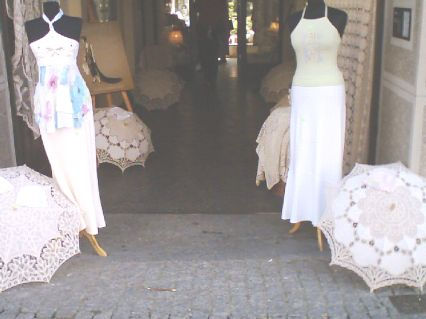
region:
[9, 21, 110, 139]
white and blue dress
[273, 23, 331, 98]
yellow dress on mannequin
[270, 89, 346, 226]
white dress on mannequin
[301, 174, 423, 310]
white and brown umbrella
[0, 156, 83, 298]
pink and white umbrella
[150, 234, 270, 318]
sidewalk is light grey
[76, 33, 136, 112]
painting on easel near umbrella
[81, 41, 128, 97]
person shown on painting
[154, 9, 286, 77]
white lights in building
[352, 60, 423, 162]
white wall near umbrella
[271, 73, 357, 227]
white skirt on black mannequin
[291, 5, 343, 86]
white tank with embroidery on mannequin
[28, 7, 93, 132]
rainbow tank on mannequin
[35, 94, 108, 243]
white skirt on mannequin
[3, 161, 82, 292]
white umbrella with black lace design around edge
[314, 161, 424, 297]
white umbrella with overall black design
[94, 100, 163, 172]
open pink white and black umbrella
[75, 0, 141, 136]
wooden easel holding oil portrait of woman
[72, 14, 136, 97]
oil portrait of woman from 1920's wearing balck evening gown and carrying ostrich feather fan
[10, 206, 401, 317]
brick walkway in grey leading up to store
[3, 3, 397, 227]
open doorway of store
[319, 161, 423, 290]
top of lace umbrella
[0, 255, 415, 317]
cobblestones in ground surface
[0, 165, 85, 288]
open umbrella on ground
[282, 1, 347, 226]
dress on black mannequin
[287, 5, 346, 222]
white dress with thin straps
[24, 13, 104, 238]
white dress on mannequin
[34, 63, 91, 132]
designs on middle of dress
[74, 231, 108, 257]
wood stand under display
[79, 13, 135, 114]
painting displayed on easel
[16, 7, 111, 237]
a dress on a dummy.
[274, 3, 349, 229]
a white dress on a dummy.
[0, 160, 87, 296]
a white umbrella on the ground.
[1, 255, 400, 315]
a cobble stone ground.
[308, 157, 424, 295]
a lacy white umbrella.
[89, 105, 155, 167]
an open white umbrella.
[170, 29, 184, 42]
a light inside of a building.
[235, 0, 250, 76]
a strong pillar in a room.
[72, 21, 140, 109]
a painting on a wooden structure.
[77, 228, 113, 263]
a piece of wood.